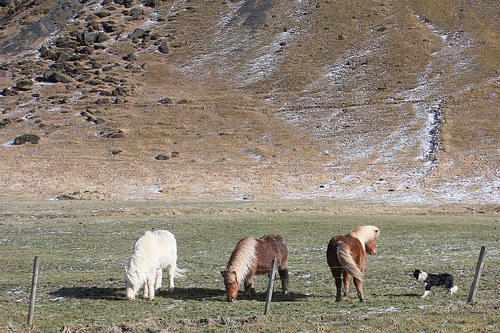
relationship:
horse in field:
[326, 225, 378, 301] [3, 197, 499, 332]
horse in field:
[220, 236, 289, 299] [3, 197, 499, 332]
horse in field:
[126, 230, 185, 300] [3, 197, 499, 332]